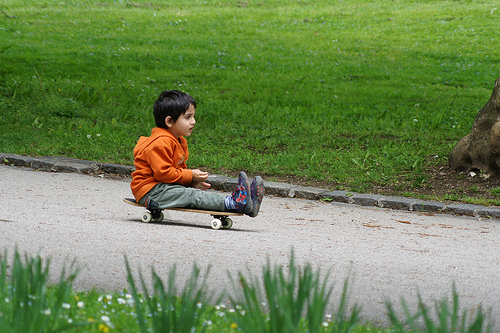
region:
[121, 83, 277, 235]
Boy on a board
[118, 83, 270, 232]
Boy is on a board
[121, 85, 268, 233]
Boy on a skateboard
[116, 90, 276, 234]
Boy is on a skateboard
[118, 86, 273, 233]
Boy sitting on a board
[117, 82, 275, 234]
Boy is sitting on a board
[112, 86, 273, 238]
Boy sitting on a skateboard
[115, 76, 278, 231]
Boy is sitting on a skateboard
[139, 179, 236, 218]
Boy is wearing pants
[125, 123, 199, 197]
Boy is wearing an orange sweatshirt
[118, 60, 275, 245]
a little boy on skateboard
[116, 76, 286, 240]
a boy sitting on skateboard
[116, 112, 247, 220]
orange shirt and gray pants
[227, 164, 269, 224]
red and blue shoes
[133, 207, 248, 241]
white wheels on skateboard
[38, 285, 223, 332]
tiny white flowers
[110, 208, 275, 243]
shadow from skateboard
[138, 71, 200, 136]
black hair on head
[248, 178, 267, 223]
black and red bottom of shoe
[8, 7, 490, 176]
grass on the ground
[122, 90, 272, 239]
boy sitting on skate board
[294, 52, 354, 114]
short green and yellow grass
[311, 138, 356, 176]
short green and yellow grass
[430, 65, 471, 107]
short green and yellow grass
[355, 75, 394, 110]
short green and yellow grass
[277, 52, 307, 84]
short green and yellow grass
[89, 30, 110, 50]
short green and yellow grass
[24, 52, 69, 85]
short green and yellow grass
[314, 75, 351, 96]
short green and yellow grass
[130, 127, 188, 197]
an orange hooded sweater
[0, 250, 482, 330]
the blades of grass are standing tall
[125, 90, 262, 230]
a little boy sitting on a skateboard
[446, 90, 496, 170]
the trunk of a tree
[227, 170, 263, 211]
blue and red tennis shoes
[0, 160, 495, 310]
a gray walk way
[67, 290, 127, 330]
small white and yellow flowers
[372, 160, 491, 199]
a patch of dirt around the tree trunk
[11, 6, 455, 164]
grass behind the child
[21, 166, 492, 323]
pavement under the child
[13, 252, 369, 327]
tall grass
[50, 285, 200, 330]
flowers next to the tall grass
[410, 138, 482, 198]
dirt by the tree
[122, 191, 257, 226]
the skateboard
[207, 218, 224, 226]
a white wheel on the skateboard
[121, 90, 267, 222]
a child wearing an orange shirt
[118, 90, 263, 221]
a child riding a skateboard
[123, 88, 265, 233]
little boy wearing an orange hoodie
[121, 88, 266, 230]
little boy sitting on a skateboard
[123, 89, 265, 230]
little boy with black hair skateboarding on a gray path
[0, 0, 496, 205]
field of lush green grass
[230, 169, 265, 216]
gray sneakers with blue and pink shoelaces and trim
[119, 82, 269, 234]
small boy sitting on skateboard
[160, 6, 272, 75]
white flowers in green grass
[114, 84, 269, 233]
small boy in orange sitting on skateboard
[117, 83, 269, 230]
small boy with black hair sitting on skateboard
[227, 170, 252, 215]
small blue and red shoe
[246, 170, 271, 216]
small blue and red shoe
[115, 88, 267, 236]
small boy in green pants sitting on skateboard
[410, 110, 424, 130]
white flower in green grass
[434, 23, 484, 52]
white flowers in green grass